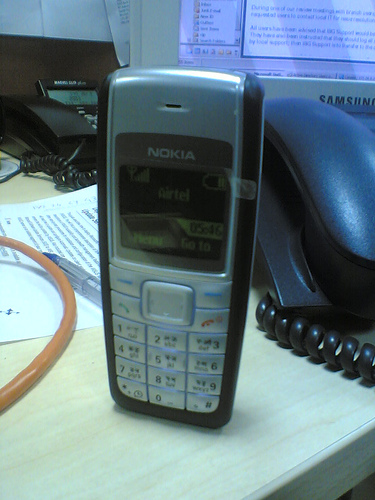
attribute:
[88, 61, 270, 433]
phone on table — standing up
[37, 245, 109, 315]
pen is on table — ball point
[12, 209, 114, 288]
notes on paper — white, under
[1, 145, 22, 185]
dish is white — light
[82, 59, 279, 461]
phone — black 